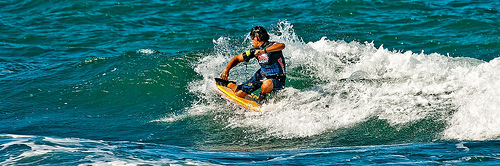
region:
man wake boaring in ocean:
[156, 28, 313, 119]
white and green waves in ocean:
[289, 31, 342, 82]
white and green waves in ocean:
[273, 109, 302, 137]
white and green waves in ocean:
[294, 101, 338, 149]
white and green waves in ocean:
[317, 41, 350, 97]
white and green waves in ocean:
[343, 109, 403, 164]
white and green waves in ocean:
[349, 39, 399, 101]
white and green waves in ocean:
[418, 76, 458, 133]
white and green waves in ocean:
[452, 61, 484, 115]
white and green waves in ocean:
[393, 101, 454, 151]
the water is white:
[308, 78, 385, 120]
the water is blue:
[2, 53, 169, 164]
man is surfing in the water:
[218, 25, 290, 111]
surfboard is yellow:
[211, 82, 256, 107]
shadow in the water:
[323, 63, 411, 97]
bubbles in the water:
[20, 138, 87, 158]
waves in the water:
[455, 63, 498, 135]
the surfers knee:
[258, 78, 272, 95]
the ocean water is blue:
[12, 51, 190, 161]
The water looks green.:
[27, 15, 169, 140]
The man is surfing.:
[179, 8, 326, 142]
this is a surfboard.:
[194, 76, 300, 153]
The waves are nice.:
[291, 45, 456, 157]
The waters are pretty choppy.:
[53, 9, 469, 153]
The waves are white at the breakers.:
[313, 48, 495, 143]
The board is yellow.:
[206, 70, 286, 132]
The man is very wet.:
[210, 25, 313, 121]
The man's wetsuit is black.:
[240, 40, 299, 107]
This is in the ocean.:
[18, 13, 455, 148]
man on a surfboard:
[215, 21, 285, 111]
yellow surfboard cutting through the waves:
[215, 72, 255, 107]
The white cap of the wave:
[200, 40, 495, 142]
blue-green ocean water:
[5, 0, 496, 160]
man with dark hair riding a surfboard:
[215, 20, 286, 115]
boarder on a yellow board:
[215, 27, 285, 109]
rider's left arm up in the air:
[255, 40, 280, 50]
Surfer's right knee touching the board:
[225, 80, 250, 95]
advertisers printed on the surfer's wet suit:
[255, 55, 285, 70]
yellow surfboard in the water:
[215, 80, 261, 108]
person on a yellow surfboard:
[197, 20, 294, 120]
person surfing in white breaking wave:
[152, 19, 379, 146]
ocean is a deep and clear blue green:
[55, 36, 177, 135]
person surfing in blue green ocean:
[167, 20, 336, 125]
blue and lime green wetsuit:
[240, 47, 288, 91]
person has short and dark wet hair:
[242, 24, 276, 51]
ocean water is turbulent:
[25, 3, 454, 155]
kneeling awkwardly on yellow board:
[198, 66, 285, 113]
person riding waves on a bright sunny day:
[56, 13, 443, 147]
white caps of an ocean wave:
[299, 39, 490, 149]